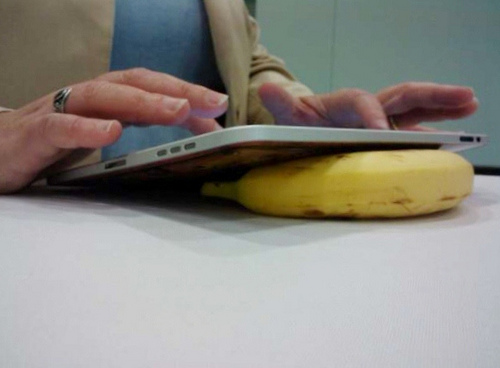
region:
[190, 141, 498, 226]
yellow banana with brown spots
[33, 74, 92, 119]
ring worn on a finger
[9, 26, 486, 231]
two hands using a tablet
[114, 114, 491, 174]
tablet with a white rim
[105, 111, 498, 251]
tablet propped up on a banana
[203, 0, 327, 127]
brown jacket sleeve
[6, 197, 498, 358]
gray table being used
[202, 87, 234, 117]
long fingernails of the person depicted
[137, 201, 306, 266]
shadow of the tablet on table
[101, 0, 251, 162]
light blue shirt worn under jacket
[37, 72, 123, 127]
person is wearing a ring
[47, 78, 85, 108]
the ring is silver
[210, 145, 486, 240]
the banana is yellow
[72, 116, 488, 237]
banana under the tablet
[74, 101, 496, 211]
the tablet is white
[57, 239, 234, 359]
the table is white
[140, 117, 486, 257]
banana is on the table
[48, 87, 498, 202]
the tablet is rectangle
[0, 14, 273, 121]
the blazer is brown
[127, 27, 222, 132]
the shirt is blue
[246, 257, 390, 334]
part of a white table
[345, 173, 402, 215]
part of a banana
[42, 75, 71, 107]
a ring on a finger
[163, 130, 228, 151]
edge of an i pad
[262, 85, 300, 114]
left thumb of a person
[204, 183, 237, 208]
tip of a banana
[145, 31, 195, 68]
part of a blue t shirt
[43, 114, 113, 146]
small finger of the right hand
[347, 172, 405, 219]
part of a banana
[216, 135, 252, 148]
edge of an i pad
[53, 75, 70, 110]
ring on a finger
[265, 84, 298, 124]
thumb of the left and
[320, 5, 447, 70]
part of a white wall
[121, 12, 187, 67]
part of a blue t shirt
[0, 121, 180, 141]
small finger of the right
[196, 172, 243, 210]
tip of the banana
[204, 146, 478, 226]
a yellow banana supporting a tablet computer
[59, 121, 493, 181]
tablet computer resting on a banana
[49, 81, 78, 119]
a ring on person's finger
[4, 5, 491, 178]
a person using a tablet computer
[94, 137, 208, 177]
buttons on the side of tablet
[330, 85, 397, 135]
left index finger tapping on tablet screen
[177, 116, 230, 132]
right index finger tapping on tablet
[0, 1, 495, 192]
a person wearing beige sport coat using tablet computer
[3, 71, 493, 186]
fingers tapping on tablet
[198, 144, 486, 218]
banana underneath a tablet computer